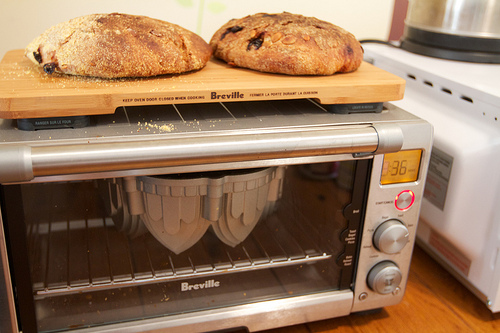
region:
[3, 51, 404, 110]
a wooden board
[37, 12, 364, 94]
bread on top of a board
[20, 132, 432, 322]
a silver microwave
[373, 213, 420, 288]
dials on the microwave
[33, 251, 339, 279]
a silver rack in the microwave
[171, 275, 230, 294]
writing on the door of the microwave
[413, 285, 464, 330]
the wooden table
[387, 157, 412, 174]
the timer on the microwave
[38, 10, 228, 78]
a piece of bread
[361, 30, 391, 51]
a black cord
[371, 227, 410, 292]
two grey knobs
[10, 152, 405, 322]
a toaster oven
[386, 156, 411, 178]
numbers on the oven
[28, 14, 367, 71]
two items on the cutting board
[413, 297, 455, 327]
a wooden counter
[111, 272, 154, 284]
a grey rack in the oven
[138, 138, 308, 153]
the handle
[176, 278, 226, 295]
brand of the oven toaster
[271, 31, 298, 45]
oats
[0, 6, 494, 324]
Toaster oven on a table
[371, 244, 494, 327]
Table made of wood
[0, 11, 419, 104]
Baked goods on a tray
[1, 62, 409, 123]
Wooden tray on a toaster oven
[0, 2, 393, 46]
White wall behind the toaster oven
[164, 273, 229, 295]
The toaster oven brand is Breville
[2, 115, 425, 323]
Silver toaster oven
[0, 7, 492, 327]
No people in the photo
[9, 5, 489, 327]
The photo is well lit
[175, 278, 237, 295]
Breville logo on appliance.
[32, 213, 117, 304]
Metal grill on the appliance.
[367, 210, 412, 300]
Two silver knobs.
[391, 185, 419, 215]
A silver button with red light.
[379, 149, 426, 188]
A display window with an orange light.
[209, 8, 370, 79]
Baked good with raisins and oats.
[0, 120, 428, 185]
Silver handle for oven door.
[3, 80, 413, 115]
Wooden cutting board.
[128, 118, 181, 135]
Small brown bread crumbs.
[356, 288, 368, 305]
Mini silver button.